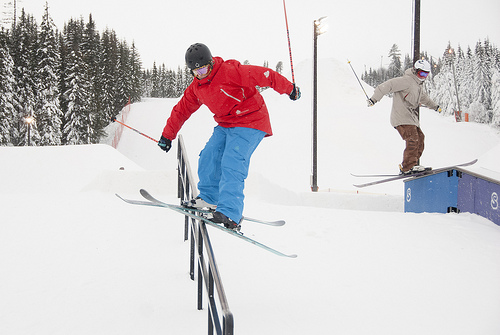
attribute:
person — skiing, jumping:
[156, 42, 301, 231]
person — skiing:
[368, 57, 443, 177]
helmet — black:
[184, 43, 213, 75]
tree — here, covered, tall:
[2, 1, 195, 145]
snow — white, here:
[2, 80, 498, 334]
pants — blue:
[199, 124, 268, 225]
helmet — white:
[413, 58, 431, 74]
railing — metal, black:
[177, 133, 234, 335]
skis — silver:
[115, 189, 299, 259]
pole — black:
[312, 19, 318, 190]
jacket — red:
[161, 57, 295, 140]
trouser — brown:
[395, 124, 425, 173]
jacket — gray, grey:
[369, 68, 438, 127]